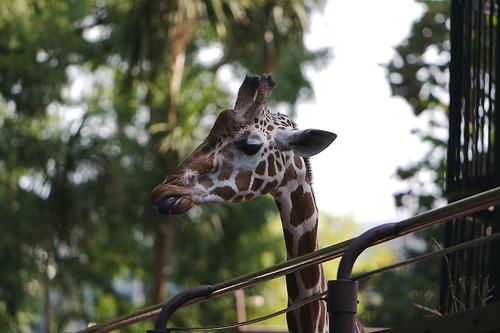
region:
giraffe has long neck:
[180, 101, 355, 303]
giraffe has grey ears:
[265, 112, 325, 166]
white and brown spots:
[267, 174, 315, 320]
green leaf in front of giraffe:
[138, 173, 498, 323]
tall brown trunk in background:
[140, 0, 196, 291]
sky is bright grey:
[312, 26, 375, 185]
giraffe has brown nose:
[126, 181, 203, 227]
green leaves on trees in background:
[30, 1, 150, 198]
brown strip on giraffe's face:
[195, 116, 229, 177]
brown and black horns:
[210, 51, 288, 126]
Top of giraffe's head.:
[142, 63, 339, 220]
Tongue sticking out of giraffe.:
[159, 190, 185, 216]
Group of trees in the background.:
[18, 56, 118, 216]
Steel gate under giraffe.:
[356, 226, 463, 331]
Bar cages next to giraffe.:
[445, 0, 492, 308]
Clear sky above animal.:
[336, 17, 386, 135]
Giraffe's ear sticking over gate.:
[265, 126, 340, 155]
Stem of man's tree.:
[166, 33, 191, 135]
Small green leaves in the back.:
[387, 45, 430, 129]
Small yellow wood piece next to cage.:
[227, 291, 262, 328]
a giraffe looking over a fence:
[138, 82, 368, 329]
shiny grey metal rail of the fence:
[371, 192, 487, 227]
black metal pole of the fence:
[326, 236, 373, 331]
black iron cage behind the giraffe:
[440, 18, 499, 266]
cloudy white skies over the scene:
[328, 89, 392, 161]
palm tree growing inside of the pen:
[104, 1, 233, 286]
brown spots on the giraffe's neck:
[277, 216, 324, 287]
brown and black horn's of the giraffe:
[228, 70, 283, 117]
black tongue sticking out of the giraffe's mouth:
[145, 187, 187, 213]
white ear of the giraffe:
[278, 125, 334, 159]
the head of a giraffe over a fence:
[158, 79, 370, 331]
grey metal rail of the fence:
[401, 192, 491, 225]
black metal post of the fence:
[323, 235, 385, 332]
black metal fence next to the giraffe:
[428, 14, 498, 258]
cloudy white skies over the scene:
[321, 23, 397, 185]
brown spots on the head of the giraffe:
[218, 158, 300, 193]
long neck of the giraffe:
[282, 176, 319, 331]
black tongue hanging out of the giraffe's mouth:
[148, 189, 190, 217]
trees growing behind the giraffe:
[9, 4, 209, 274]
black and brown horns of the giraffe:
[218, 70, 277, 117]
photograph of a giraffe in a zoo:
[32, 15, 472, 324]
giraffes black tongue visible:
[145, 178, 192, 230]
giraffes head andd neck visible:
[149, 55, 352, 330]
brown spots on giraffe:
[205, 160, 245, 198]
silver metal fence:
[147, 196, 497, 322]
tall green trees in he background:
[9, 0, 322, 323]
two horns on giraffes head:
[222, 62, 283, 128]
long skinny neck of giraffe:
[279, 183, 343, 325]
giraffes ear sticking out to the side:
[273, 118, 341, 163]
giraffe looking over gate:
[154, 78, 356, 331]